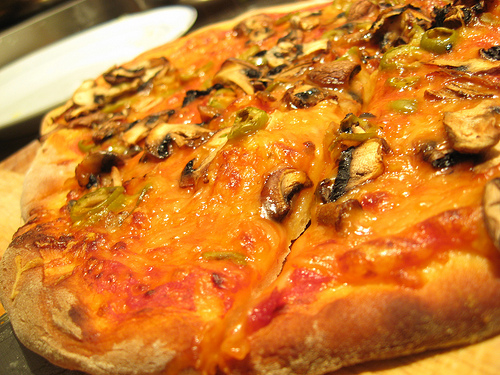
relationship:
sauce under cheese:
[75, 255, 200, 322] [38, 91, 347, 358]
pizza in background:
[35, 0, 488, 137] [7, 0, 199, 120]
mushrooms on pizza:
[256, 132, 409, 231] [2, 0, 496, 374]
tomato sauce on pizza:
[279, 232, 450, 318] [2, 0, 496, 374]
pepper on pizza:
[70, 183, 153, 227] [2, 0, 496, 374]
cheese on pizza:
[44, 0, 485, 374] [2, 0, 496, 374]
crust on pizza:
[5, 207, 59, 257] [0, 0, 500, 372]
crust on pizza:
[246, 220, 467, 357] [15, 29, 452, 373]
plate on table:
[1, 4, 198, 130] [327, 330, 499, 373]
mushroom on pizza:
[262, 171, 311, 221] [119, 170, 296, 270]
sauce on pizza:
[248, 265, 332, 332] [2, 0, 496, 374]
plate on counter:
[1, 4, 198, 139] [3, 5, 241, 75]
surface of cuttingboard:
[399, 344, 484, 370] [344, 342, 499, 374]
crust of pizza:
[263, 266, 494, 320] [40, 61, 482, 320]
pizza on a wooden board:
[0, 0, 500, 372] [377, 355, 481, 373]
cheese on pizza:
[378, 177, 471, 232] [2, 0, 496, 374]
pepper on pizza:
[420, 29, 457, 54] [0, 0, 500, 372]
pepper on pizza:
[73, 192, 130, 220] [0, 0, 500, 372]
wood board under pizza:
[335, 332, 499, 372] [2, 0, 496, 374]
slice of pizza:
[0, 94, 370, 374] [2, 0, 496, 374]